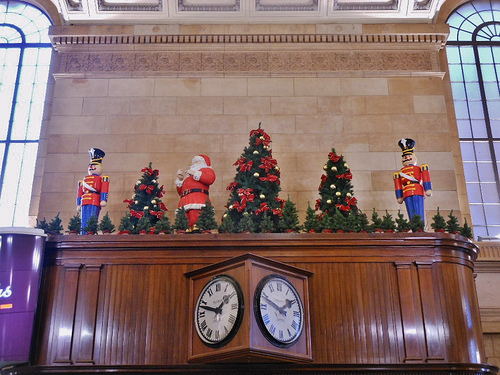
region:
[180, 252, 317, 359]
two round clocks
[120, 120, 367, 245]
three trees with red bows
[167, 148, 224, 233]
santa claus facing the left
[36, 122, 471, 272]
christmas scene on a mantel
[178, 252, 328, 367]
two views of the time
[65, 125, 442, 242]
two nutcrackers at the end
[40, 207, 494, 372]
podium made of wood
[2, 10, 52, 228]
a long window with sun shining in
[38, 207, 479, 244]
a row of tiny christmas trees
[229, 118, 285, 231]
tree with gold balls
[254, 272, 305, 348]
The face of a clock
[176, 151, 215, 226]
A figurine of Santa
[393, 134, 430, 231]
A nutcracker doll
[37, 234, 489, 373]
A wooden mantle with clocks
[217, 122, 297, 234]
A small, decorated Christmas tree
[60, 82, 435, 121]
A tan brick wall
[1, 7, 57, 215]
The edge of a pane window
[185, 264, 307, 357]
Two clocks facing in opposite directions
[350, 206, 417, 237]
A row of tiny evergreen trees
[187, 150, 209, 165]
The head of a small Santa figurine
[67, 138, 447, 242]
Christmas display in building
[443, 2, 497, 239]
Large arch window with black trim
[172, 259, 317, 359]
Two clocks with white faces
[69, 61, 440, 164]
Wall made of brick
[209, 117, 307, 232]
Christmas tree with red bows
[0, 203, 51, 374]
Part of a purple sign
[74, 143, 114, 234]
The nutcracker mannequin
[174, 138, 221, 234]
A santa claus figure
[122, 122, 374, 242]
Three trees decorated with red and gold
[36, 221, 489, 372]
A brown wooden platform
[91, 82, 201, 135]
brown brick wall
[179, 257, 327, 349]
a clock with two faces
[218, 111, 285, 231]
a Christmas tree with red bows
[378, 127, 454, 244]
wooden soldier in red and blue uniform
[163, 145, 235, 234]
statue of Santa Clause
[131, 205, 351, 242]
several small Christmas trees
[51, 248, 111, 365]
wood engraved decorative pillars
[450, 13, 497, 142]
a window with many small glass panes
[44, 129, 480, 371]
Christmas decorations on a wooden shelf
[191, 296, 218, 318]
the minute hand on a clock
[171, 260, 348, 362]
Two clocks on the sides of a half cube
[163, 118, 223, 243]
A model Santa Claus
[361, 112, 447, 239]
A toy soldier decoration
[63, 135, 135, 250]
A Nutcracker style soldier decoration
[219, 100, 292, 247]
A decorated small Christmas tree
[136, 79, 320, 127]
Marble bricks on a wall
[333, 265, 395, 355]
The side of a wooden display podium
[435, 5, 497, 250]
One side of a curved paned window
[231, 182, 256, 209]
A decorative Christmas bow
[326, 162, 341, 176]
A small golden Christmas ornament